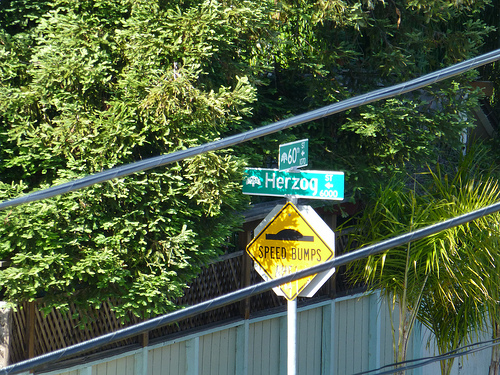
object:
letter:
[277, 177, 284, 189]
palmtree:
[373, 160, 498, 370]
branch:
[163, 234, 190, 266]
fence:
[10, 251, 246, 364]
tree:
[242, 48, 444, 229]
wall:
[191, 326, 243, 374]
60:
[287, 147, 297, 164]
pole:
[0, 159, 165, 214]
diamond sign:
[246, 202, 334, 302]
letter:
[285, 178, 291, 188]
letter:
[266, 172, 276, 188]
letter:
[310, 178, 318, 195]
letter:
[292, 178, 299, 190]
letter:
[300, 178, 308, 190]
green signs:
[238, 165, 345, 202]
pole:
[283, 190, 297, 374]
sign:
[278, 138, 309, 170]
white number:
[287, 148, 293, 164]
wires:
[396, 62, 479, 90]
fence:
[373, 260, 500, 375]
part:
[210, 348, 218, 356]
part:
[115, 226, 128, 235]